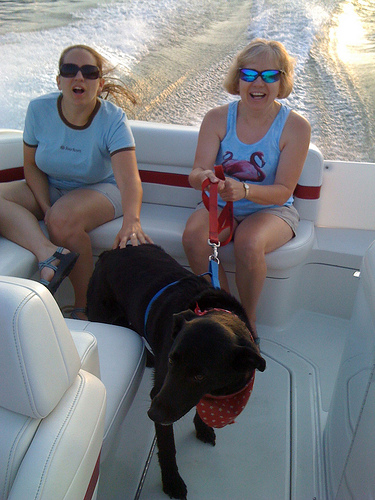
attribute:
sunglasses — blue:
[236, 65, 283, 83]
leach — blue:
[196, 163, 238, 295]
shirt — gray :
[202, 102, 294, 216]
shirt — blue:
[21, 90, 137, 192]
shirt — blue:
[211, 99, 293, 209]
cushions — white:
[9, 128, 370, 498]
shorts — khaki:
[48, 181, 124, 216]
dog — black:
[71, 242, 271, 499]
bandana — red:
[198, 306, 252, 430]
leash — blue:
[209, 256, 221, 288]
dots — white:
[196, 383, 251, 425]